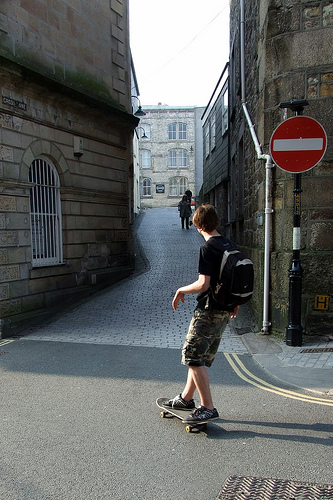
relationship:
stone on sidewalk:
[262, 347, 295, 366] [241, 326, 322, 399]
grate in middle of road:
[215, 474, 332, 498] [1, 338, 332, 496]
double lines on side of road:
[222, 352, 333, 407] [4, 207, 331, 491]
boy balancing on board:
[171, 204, 254, 424] [156, 396, 209, 433]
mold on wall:
[1, 36, 119, 104] [1, 0, 133, 115]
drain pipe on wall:
[239, 0, 273, 332] [227, 1, 321, 336]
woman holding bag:
[176, 195, 193, 231] [188, 217, 192, 226]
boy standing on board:
[168, 204, 259, 429] [156, 396, 209, 433]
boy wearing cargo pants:
[171, 204, 254, 424] [180, 304, 228, 365]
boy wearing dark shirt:
[171, 204, 254, 424] [194, 235, 230, 311]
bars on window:
[27, 158, 58, 257] [28, 153, 66, 269]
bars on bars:
[27, 158, 58, 257] [27, 158, 58, 257]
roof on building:
[135, 105, 196, 110] [137, 112, 194, 212]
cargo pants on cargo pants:
[180, 304, 228, 365] [180, 304, 228, 365]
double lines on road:
[222, 352, 332, 410] [1, 338, 332, 496]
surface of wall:
[62, 6, 95, 36] [7, 1, 133, 275]